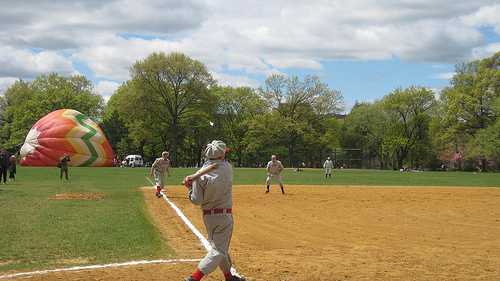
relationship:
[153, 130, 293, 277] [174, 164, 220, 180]
player swinging bat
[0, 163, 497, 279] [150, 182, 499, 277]
field covered in dirt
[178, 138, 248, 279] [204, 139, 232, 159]
player wearing hat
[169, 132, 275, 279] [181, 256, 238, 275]
boy wearing socks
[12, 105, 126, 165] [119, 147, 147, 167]
parachute by van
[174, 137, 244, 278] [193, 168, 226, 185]
person holding bat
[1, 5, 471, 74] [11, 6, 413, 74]
clouds in sky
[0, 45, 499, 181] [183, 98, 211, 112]
trees with leaves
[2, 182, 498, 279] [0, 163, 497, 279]
dirt on field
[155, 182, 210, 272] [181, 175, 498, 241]
line in dirt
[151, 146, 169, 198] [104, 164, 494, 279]
people on field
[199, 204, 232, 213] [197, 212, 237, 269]
belt on pants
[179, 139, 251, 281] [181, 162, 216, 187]
boy swinging baseball bat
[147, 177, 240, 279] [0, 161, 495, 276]
white line on ground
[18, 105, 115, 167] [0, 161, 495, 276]
balloon on ground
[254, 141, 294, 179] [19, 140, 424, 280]
person standing in field